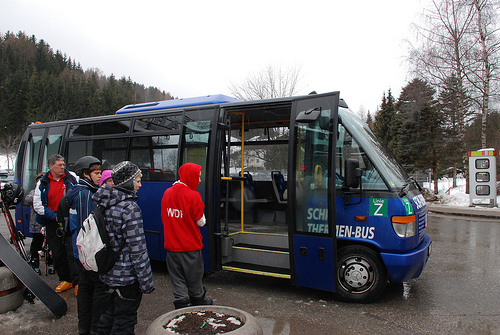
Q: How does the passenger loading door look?
A: Open.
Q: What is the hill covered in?
A: Trees.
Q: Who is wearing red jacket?
A: A person.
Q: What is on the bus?
A: An open door.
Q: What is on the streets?
A: Moisture.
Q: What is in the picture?
A: A man.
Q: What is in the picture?
A: A man.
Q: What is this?
A: A van.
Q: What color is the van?
A: Blue.